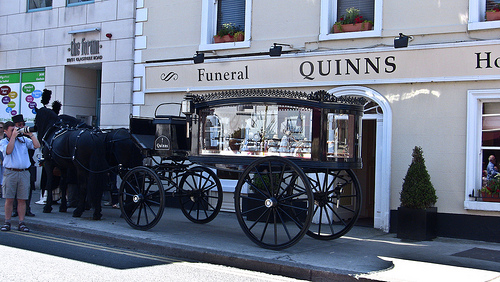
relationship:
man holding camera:
[0, 119, 48, 235] [9, 116, 46, 141]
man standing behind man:
[1, 112, 40, 219] [0, 119, 48, 235]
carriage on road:
[111, 85, 365, 252] [1, 212, 498, 279]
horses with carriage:
[29, 98, 153, 223] [111, 85, 365, 252]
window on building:
[199, 0, 251, 52] [1, 0, 498, 246]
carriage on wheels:
[118, 89, 363, 250] [124, 157, 390, 231]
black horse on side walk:
[34, 90, 107, 220] [0, 190, 500, 282]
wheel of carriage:
[227, 155, 323, 262] [118, 89, 363, 250]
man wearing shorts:
[0, 119, 48, 235] [0, 166, 36, 201]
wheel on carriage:
[234, 155, 314, 250] [111, 85, 365, 252]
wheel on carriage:
[290, 160, 365, 241] [111, 85, 365, 252]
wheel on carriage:
[120, 166, 167, 226] [111, 85, 365, 252]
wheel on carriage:
[179, 166, 220, 221] [111, 85, 365, 252]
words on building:
[181, 45, 487, 105] [138, 7, 493, 118]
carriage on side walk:
[111, 85, 365, 252] [0, 190, 500, 282]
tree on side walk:
[396, 146, 438, 239] [332, 238, 494, 272]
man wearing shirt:
[0, 119, 48, 235] [1, 137, 31, 167]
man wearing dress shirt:
[0, 112, 55, 242] [3, 135, 33, 169]